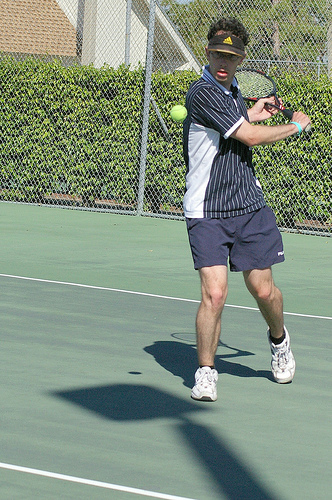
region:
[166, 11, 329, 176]
guy swinging tennis racquet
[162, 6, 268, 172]
green tennis ball near player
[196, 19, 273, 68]
black and yellow visor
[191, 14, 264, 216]
guy wearing blue and white shirt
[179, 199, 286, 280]
blue shorts with white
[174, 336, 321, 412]
white tennis shoes and laces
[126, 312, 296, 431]
shadow of tennis player on court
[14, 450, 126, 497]
chalk line on tennis court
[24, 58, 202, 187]
green bush hedge behind fence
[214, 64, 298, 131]
black and red tennis racquet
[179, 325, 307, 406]
White shoes on a tennis player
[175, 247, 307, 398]
Legs on a tennis player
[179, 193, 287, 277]
Shorts on a tennis player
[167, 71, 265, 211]
Shirt on a tennis player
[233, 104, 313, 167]
Arm on a tennis player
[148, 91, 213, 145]
Green ball in the air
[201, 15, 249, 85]
Head on a man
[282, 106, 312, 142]
Bracelet on a man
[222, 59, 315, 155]
Racquet in a hand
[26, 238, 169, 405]
Green and white tennis court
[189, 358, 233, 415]
A white pair of sneakers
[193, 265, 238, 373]
a mans hairy leg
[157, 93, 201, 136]
a yellow tennis ball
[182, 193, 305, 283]
A pair of black shorts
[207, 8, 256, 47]
a mans curly black hair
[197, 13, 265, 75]
A man wearing a black sun visor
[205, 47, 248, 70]
a man wearing a pair of glasses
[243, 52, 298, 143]
a man holding a tennis racket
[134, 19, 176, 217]
a fence around a tennis court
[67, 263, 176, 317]
a white line on the tennis court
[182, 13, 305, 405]
a brunette man playing tennis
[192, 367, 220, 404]
the white tennis sneaker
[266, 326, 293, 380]
the white tennis sneaker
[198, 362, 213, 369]
the short black sock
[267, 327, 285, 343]
the short black sock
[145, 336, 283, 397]
the shadow of the man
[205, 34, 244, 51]
the visor of the man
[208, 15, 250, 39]
the curly hair of the man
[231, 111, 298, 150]
the bare arm of the man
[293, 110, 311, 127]
the hand of the man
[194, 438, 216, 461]
A shadow is visible.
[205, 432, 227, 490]
A shadow is visible.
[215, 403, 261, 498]
A shadow is visible.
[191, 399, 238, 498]
A shadow is visible.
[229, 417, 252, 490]
A shadow is visible.